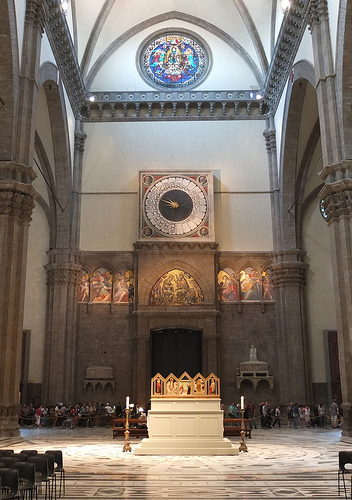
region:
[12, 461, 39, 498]
the chair is black in color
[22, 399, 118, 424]
many people are sitting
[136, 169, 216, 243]
a large clock on the wall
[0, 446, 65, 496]
chairs are empty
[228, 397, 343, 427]
people are standing in a line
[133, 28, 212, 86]
the window is colorful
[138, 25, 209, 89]
the window resembles a person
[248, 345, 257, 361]
a white statue near the wall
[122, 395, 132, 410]
a white candle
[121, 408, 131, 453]
the candle stand is a golden color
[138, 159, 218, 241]
this is a clock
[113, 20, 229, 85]
This is a stained glass window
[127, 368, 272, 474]
This is an altar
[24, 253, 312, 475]
This is inside a church.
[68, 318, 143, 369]
This is a wall made of stone.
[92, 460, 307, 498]
The floor is decorated tile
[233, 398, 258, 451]
This is a candle holder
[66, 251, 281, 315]
These paintings are classical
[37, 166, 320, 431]
this is a gothic style building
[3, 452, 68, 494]
The chairs are black.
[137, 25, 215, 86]
circular stained glass window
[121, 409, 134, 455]
tall, gold candlestick holder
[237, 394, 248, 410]
large white cnadle on the holder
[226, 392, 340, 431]
a group of people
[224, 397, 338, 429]
people walking through the room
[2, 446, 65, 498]
chairs organized in rows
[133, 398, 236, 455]
large white pedestal in the middle of the room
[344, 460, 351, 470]
hole on the back of the chair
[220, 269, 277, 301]
paintings of people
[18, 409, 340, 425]
rope keeping people from fully entering the room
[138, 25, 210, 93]
The Glass painting of the church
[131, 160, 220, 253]
The dark black clock of the painting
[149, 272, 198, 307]
The center painting of the church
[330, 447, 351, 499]
A black chair in the background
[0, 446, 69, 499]
A set of black chairs in the background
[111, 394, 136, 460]
A candle stick on the left of the Altar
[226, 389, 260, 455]
A candle stick on the right of the Altar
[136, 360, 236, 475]
The central religious altar of the church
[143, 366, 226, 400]
A central set of paintings in the altar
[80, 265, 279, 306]
A central set of painings in the middle of the church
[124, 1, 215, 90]
This is classical art.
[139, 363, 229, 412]
This is a religious alter.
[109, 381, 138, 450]
The candle stand is tall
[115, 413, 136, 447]
The stand is made of metal.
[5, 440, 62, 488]
These are chairs.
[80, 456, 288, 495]
The floor is made of stone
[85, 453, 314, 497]
The floor is decorated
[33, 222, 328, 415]
This is gothic architecture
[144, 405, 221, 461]
The base of the altar is white